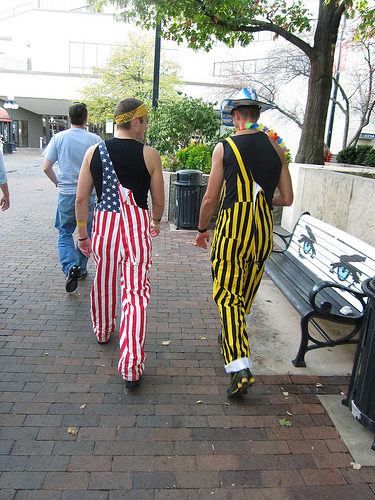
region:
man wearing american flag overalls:
[76, 78, 164, 379]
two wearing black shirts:
[75, 104, 298, 402]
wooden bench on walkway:
[258, 208, 357, 374]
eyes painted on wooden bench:
[296, 223, 359, 289]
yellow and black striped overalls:
[216, 140, 282, 366]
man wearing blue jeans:
[44, 104, 105, 284]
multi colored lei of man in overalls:
[240, 117, 297, 161]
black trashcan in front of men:
[168, 166, 209, 229]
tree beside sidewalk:
[156, 5, 360, 146]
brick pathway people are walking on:
[0, 143, 348, 498]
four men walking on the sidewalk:
[0, 84, 293, 399]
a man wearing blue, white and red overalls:
[74, 98, 165, 389]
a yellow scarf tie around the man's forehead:
[106, 103, 148, 125]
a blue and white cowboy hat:
[219, 88, 274, 127]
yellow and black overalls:
[210, 136, 274, 371]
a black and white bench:
[272, 211, 374, 366]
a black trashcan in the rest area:
[173, 169, 207, 231]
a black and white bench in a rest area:
[263, 211, 373, 366]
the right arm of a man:
[0, 147, 11, 212]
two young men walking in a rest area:
[75, 86, 294, 398]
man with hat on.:
[210, 81, 271, 382]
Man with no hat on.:
[78, 91, 161, 403]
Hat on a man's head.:
[209, 78, 281, 115]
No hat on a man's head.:
[102, 89, 164, 139]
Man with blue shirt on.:
[45, 101, 93, 297]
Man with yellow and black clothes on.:
[217, 82, 270, 412]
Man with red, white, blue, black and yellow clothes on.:
[68, 92, 161, 412]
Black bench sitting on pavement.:
[226, 199, 369, 372]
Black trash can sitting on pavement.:
[167, 161, 212, 231]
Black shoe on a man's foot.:
[43, 262, 84, 295]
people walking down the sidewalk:
[21, 78, 294, 405]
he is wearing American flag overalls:
[77, 141, 163, 377]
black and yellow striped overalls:
[198, 129, 282, 396]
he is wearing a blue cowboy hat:
[221, 83, 276, 122]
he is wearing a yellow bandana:
[102, 92, 149, 125]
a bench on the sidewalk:
[261, 214, 372, 368]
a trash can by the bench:
[341, 268, 371, 446]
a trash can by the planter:
[171, 164, 204, 232]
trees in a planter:
[146, 77, 222, 221]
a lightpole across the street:
[2, 94, 20, 154]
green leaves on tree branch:
[94, 1, 308, 52]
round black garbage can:
[172, 169, 206, 229]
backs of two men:
[76, 89, 293, 394]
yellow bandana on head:
[110, 98, 146, 135]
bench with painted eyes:
[291, 215, 374, 290]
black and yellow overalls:
[212, 137, 274, 373]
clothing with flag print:
[90, 141, 151, 381]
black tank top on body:
[86, 136, 156, 206]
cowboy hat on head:
[218, 85, 278, 127]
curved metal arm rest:
[308, 281, 366, 318]